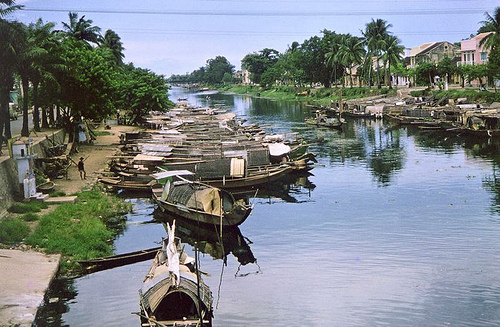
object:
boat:
[98, 163, 315, 189]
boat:
[113, 150, 323, 176]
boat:
[128, 132, 292, 153]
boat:
[111, 141, 308, 163]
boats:
[308, 92, 500, 136]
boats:
[148, 169, 253, 229]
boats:
[135, 100, 266, 139]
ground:
[0, 71, 500, 180]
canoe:
[75, 244, 161, 273]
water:
[48, 86, 500, 327]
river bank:
[0, 112, 148, 327]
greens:
[0, 181, 130, 264]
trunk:
[0, 104, 76, 144]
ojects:
[7, 136, 46, 202]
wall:
[0, 119, 69, 196]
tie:
[31, 182, 125, 265]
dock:
[0, 114, 150, 317]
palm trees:
[324, 14, 406, 87]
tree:
[356, 17, 404, 91]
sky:
[0, 0, 500, 59]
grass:
[39, 181, 137, 267]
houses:
[342, 31, 500, 88]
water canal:
[55, 79, 499, 327]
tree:
[415, 54, 437, 89]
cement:
[0, 250, 61, 327]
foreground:
[0, 0, 500, 142]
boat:
[305, 109, 347, 128]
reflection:
[480, 157, 500, 223]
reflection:
[364, 129, 404, 189]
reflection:
[247, 101, 440, 164]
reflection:
[196, 92, 235, 112]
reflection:
[231, 227, 264, 278]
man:
[76, 156, 87, 181]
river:
[38, 83, 499, 327]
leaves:
[309, 28, 368, 87]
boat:
[130, 220, 212, 327]